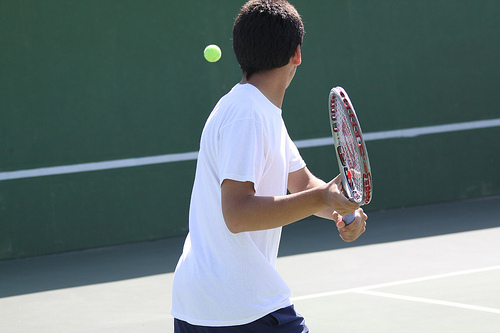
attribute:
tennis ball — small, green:
[201, 40, 226, 64]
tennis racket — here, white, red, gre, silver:
[327, 81, 371, 225]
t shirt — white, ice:
[160, 84, 311, 326]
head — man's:
[228, 0, 310, 81]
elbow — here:
[225, 192, 255, 238]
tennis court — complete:
[2, 6, 500, 331]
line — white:
[2, 109, 500, 184]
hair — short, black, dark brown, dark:
[230, 0, 311, 72]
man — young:
[166, 0, 370, 331]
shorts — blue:
[169, 305, 314, 330]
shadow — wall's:
[4, 194, 500, 299]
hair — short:
[239, 72, 252, 88]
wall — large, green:
[5, 0, 499, 253]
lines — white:
[133, 254, 500, 330]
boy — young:
[168, 6, 380, 329]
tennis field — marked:
[3, 184, 500, 327]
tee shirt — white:
[169, 78, 316, 328]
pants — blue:
[270, 311, 293, 329]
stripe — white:
[1, 115, 500, 192]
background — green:
[5, 5, 499, 253]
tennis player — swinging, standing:
[167, 4, 371, 331]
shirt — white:
[168, 79, 324, 327]